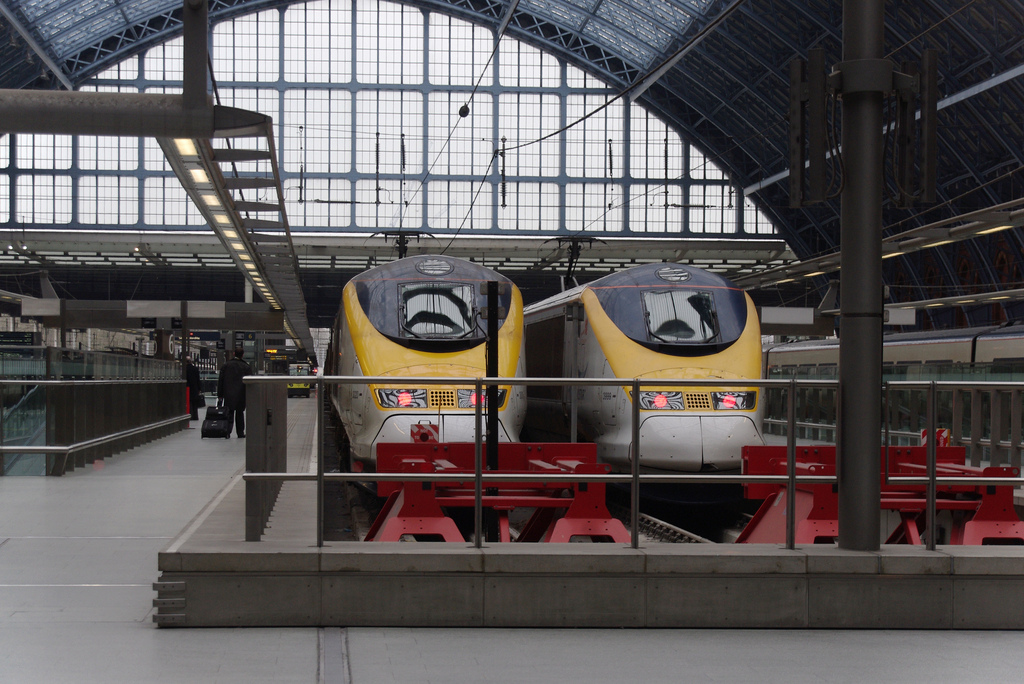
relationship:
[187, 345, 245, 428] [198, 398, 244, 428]
man pulling suitcase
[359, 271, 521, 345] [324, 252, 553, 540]
windshield on train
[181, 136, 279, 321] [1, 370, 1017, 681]
lights above platform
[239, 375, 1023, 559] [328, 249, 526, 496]
rail near train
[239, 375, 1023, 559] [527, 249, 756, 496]
rail near train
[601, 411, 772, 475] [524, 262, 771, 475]
bottom on train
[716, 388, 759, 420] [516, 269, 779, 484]
light on train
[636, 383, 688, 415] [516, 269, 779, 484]
light on train